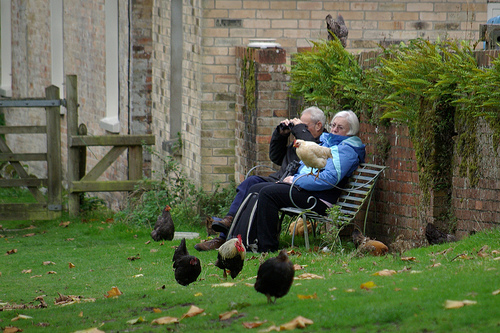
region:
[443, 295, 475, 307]
a brown leaf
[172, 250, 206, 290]
a large black bird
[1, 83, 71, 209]
part of a wooden fence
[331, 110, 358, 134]
a woman's gray hair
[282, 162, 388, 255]
part of a bench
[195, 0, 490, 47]
part of a brick building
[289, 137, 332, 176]
a large white bird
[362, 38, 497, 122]
green tree leaves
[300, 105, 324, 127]
a man's short cut gray hair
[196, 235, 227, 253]
a brown shoe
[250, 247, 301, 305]
Female chicken walking on grass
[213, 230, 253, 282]
Female chicken walking on grass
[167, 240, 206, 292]
Female chicken walking on grass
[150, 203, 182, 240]
Female chicken walking on grass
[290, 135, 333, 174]
Light brown chicken standing on a woman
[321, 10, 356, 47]
Chicken standing on a brick wall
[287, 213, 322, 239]
Female chicken walking on grass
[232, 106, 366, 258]
Older couple sitting on a bench with chickens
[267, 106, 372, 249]
Woman in a blue jacket and gray hair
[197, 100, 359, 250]
two old people seated on a bench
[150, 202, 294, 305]
black fowls on a farm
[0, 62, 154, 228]
brown wooden fence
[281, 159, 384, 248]
green metal bench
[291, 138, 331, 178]
yellow chicken on a bench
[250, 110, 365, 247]
old woman wearing light blue jacket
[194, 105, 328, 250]
old man wearing black jacket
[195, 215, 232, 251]
brown shoes of old man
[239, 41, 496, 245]
bricked wall behind bench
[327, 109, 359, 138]
short Grey Hair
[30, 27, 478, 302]
The people are sitting on a bench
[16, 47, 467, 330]
The people are watching their chickens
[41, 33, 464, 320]
Some chickens are walking around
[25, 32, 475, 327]
Some chickens are looking for food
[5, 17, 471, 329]
The people are guarding their livestock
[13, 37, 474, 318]
The people are relaxing very nicely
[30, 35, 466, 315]
The man is looking at something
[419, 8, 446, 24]
tan brick in wall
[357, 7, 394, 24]
tan brick in wall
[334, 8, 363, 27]
tan brick in wall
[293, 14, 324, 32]
tan brick in wall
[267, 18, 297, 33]
tan brick in wall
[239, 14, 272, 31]
tan brick in wall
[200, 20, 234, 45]
tan brick in wall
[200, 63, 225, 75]
tan brick in wall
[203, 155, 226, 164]
tan brick in wall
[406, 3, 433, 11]
tan brick in wall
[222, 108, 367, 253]
woman sitting on bench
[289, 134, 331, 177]
rooster sitting on bench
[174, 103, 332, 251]
man sitting on bench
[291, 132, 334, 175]
rooster on bench is white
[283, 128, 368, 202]
woman wearing big coat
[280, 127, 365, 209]
woman's coat is blue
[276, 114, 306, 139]
man looking through binoculars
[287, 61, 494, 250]
red brick wall behind bench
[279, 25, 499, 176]
shrubbery on brick wall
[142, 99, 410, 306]
a old couple sitting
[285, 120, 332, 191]
a yellow chicken on arm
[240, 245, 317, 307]
a fat black chicken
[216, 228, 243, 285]
a black and white rooster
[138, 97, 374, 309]
a couple and chickens